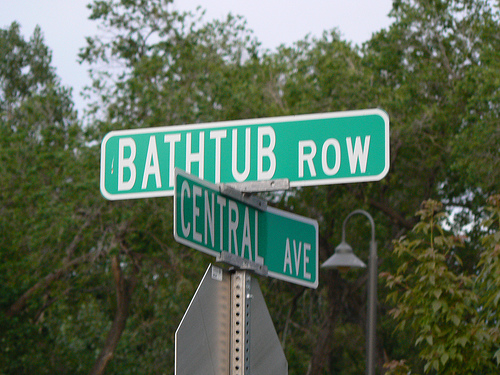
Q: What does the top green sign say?
A: BATHTUB ROW.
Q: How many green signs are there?
A: Two.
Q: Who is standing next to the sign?
A: No one.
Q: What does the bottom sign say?
A: CENTRAL AVE.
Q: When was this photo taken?
A: Daytime.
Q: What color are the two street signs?
A: Green.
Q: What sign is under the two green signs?
A: STOP sign.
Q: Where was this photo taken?
A: A city street intersection.